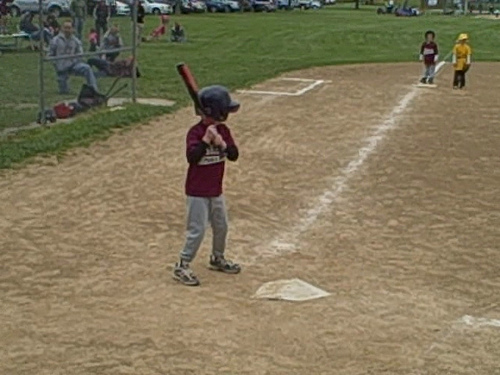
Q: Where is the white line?
A: On the field.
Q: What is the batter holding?
A: A baseball bat.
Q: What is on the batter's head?
A: A helmet.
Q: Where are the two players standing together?
A: At third base.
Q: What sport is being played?
A: Baseball.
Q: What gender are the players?
A: Male.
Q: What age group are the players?
A: Children.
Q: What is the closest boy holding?
A: A bat.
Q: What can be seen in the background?
A: Cars.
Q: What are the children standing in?
A: Dirt.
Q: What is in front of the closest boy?
A: A base.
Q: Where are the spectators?
A: On the grass.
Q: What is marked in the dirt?
A: White lines.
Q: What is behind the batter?
A: A fence.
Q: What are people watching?
A: The game.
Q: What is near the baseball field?
A: Baseball field.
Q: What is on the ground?
A: Long white line.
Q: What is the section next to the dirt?
A: Green grass.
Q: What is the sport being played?
A: Baseball.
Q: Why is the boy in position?
A: To hit the ball.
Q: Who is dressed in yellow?
A: A girl.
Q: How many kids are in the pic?
A: Three.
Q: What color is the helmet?
A: Black.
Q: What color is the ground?
A: Brown.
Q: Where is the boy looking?
A: The left.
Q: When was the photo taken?
A: Daytime.